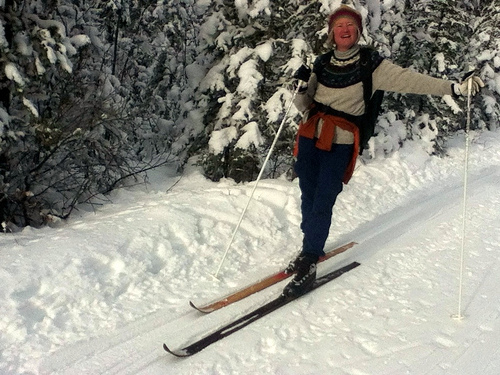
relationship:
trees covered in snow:
[13, 55, 87, 216] [202, 59, 264, 88]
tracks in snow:
[38, 262, 109, 320] [202, 59, 264, 88]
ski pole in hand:
[447, 71, 479, 322] [443, 65, 491, 99]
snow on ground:
[202, 59, 264, 88] [138, 202, 243, 224]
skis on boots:
[216, 277, 271, 329] [290, 256, 329, 286]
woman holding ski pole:
[260, 8, 426, 296] [447, 71, 479, 322]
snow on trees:
[202, 59, 264, 88] [13, 55, 87, 216]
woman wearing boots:
[260, 8, 426, 296] [290, 256, 329, 286]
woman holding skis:
[260, 8, 426, 296] [216, 277, 271, 329]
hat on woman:
[323, 3, 360, 15] [260, 8, 426, 296]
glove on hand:
[281, 55, 298, 85] [443, 65, 491, 99]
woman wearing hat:
[260, 8, 426, 296] [323, 3, 360, 15]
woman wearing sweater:
[260, 8, 426, 296] [325, 127, 337, 134]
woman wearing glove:
[260, 8, 426, 296] [281, 55, 298, 85]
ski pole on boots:
[447, 71, 479, 322] [290, 256, 329, 286]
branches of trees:
[3, 12, 98, 65] [13, 55, 87, 216]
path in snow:
[119, 93, 170, 141] [202, 59, 264, 88]